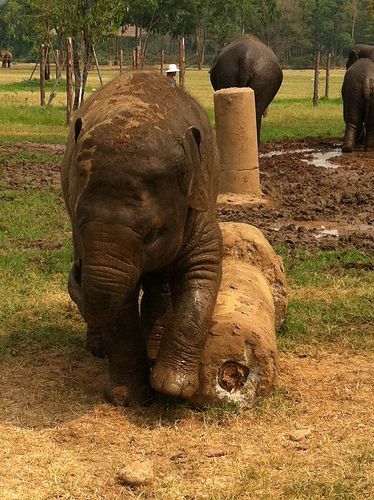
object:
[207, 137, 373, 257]
mud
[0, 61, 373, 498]
ground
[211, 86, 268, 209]
pillar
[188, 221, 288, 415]
pillar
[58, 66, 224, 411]
elephant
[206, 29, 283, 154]
elephant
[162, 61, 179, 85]
man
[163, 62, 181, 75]
hat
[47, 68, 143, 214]
mud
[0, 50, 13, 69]
elephant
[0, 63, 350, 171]
grass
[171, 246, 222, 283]
wrinkles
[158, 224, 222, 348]
leg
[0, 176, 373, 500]
grass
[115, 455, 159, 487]
rock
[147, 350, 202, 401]
foot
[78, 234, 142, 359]
trunk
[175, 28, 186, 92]
tree trunk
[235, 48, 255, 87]
tail